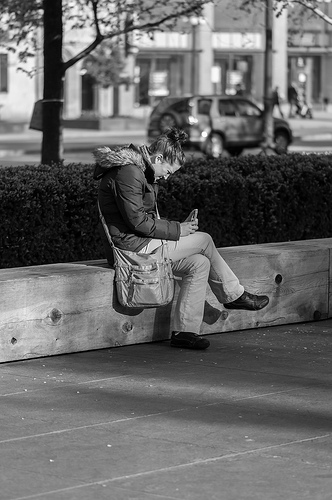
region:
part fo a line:
[45, 92, 69, 139]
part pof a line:
[213, 442, 242, 481]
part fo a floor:
[202, 401, 227, 441]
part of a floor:
[240, 451, 253, 473]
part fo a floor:
[209, 459, 230, 496]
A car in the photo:
[152, 97, 289, 152]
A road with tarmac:
[140, 405, 280, 481]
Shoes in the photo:
[167, 287, 272, 350]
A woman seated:
[96, 134, 237, 338]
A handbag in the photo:
[108, 234, 180, 317]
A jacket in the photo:
[97, 138, 167, 245]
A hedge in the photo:
[208, 158, 294, 229]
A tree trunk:
[37, 62, 64, 154]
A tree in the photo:
[32, 12, 112, 100]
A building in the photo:
[173, 30, 276, 88]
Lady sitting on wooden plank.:
[2, 126, 330, 365]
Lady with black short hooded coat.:
[92, 126, 268, 349]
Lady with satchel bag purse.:
[92, 126, 269, 350]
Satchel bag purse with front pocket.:
[110, 242, 179, 310]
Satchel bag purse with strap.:
[95, 193, 182, 309]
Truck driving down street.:
[0, 93, 331, 164]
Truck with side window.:
[145, 91, 297, 153]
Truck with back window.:
[147, 93, 297, 157]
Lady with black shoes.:
[93, 126, 269, 350]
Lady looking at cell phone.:
[92, 124, 271, 351]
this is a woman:
[22, 195, 330, 398]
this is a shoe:
[222, 263, 320, 388]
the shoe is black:
[224, 278, 242, 315]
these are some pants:
[139, 192, 215, 321]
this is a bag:
[99, 202, 153, 326]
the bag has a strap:
[105, 228, 187, 339]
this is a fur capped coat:
[107, 143, 124, 163]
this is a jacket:
[133, 198, 151, 215]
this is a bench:
[10, 243, 107, 351]